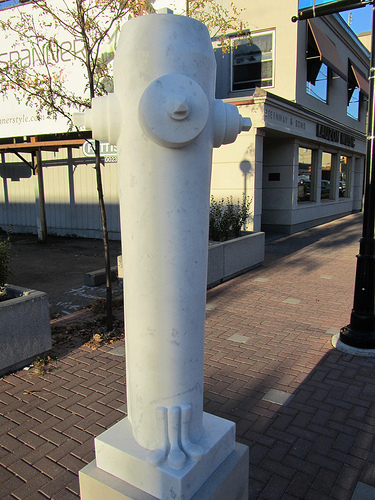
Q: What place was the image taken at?
A: It was taken at the sidewalk.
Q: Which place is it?
A: It is a sidewalk.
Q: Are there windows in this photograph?
A: Yes, there is a window.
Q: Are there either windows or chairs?
A: Yes, there is a window.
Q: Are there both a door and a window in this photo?
A: No, there is a window but no doors.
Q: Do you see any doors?
A: No, there are no doors.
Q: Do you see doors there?
A: No, there are no doors.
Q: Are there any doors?
A: No, there are no doors.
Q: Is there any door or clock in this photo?
A: No, there are no doors or clocks.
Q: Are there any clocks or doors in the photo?
A: No, there are no doors or clocks.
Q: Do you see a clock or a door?
A: No, there are no doors or clocks.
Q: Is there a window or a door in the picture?
A: Yes, there is a window.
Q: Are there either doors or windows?
A: Yes, there is a window.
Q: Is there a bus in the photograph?
A: No, there are no buses.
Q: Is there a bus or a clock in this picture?
A: No, there are no buses or clocks.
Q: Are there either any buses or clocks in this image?
A: No, there are no buses or clocks.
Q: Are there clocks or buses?
A: No, there are no buses or clocks.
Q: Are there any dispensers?
A: No, there are no dispensers.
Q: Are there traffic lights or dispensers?
A: No, there are no dispensers or traffic lights.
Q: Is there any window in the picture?
A: Yes, there is a window.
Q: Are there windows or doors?
A: Yes, there is a window.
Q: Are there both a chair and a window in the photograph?
A: No, there is a window but no chairs.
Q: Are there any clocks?
A: No, there are no clocks.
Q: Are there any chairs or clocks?
A: No, there are no clocks or chairs.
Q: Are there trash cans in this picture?
A: No, there are no trash cans.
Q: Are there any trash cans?
A: No, there are no trash cans.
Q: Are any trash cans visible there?
A: No, there are no trash cans.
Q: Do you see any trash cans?
A: No, there are no trash cans.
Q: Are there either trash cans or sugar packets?
A: No, there are no trash cans or sugar packets.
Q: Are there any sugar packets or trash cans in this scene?
A: No, there are no trash cans or sugar packets.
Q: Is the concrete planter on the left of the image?
A: Yes, the planter is on the left of the image.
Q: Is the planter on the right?
A: No, the planter is on the left of the image.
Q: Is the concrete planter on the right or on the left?
A: The planter is on the left of the image.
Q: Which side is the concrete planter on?
A: The planter is on the left of the image.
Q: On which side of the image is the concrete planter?
A: The planter is on the left of the image.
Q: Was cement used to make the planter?
A: Yes, the planter is made of cement.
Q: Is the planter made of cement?
A: Yes, the planter is made of cement.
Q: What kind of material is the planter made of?
A: The planter is made of cement.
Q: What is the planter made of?
A: The planter is made of concrete.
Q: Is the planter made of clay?
A: No, the planter is made of concrete.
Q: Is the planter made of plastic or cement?
A: The planter is made of cement.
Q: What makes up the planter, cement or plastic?
A: The planter is made of cement.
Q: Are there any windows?
A: Yes, there is a window.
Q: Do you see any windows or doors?
A: Yes, there is a window.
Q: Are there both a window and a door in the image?
A: No, there is a window but no doors.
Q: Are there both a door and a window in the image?
A: No, there is a window but no doors.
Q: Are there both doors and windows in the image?
A: No, there is a window but no doors.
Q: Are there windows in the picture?
A: Yes, there is a window.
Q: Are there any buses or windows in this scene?
A: Yes, there is a window.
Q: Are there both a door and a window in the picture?
A: No, there is a window but no doors.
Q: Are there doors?
A: No, there are no doors.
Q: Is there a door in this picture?
A: No, there are no doors.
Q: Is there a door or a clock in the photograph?
A: No, there are no doors or clocks.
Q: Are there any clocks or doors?
A: No, there are no doors or clocks.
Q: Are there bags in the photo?
A: No, there are no bags.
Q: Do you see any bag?
A: No, there are no bags.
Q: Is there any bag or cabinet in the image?
A: No, there are no bags or cabinets.